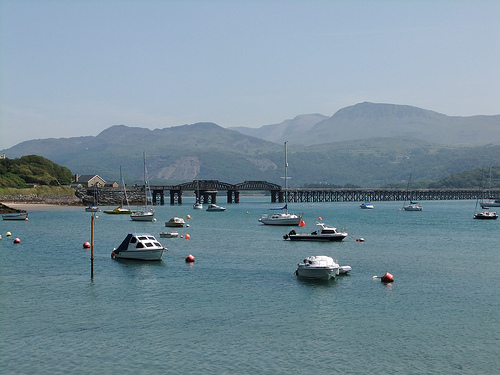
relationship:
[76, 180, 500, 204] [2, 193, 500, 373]
bridge across water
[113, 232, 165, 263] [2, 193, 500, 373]
boat on water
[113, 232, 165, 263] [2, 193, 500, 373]
boat drifting in water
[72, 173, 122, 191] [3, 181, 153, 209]
structure on bank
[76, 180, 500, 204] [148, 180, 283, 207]
bridge has suspension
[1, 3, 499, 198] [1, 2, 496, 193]
view in background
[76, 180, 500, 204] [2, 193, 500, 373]
bridge over water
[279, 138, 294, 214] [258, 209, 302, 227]
sail down on boat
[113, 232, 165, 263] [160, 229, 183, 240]
boat near boat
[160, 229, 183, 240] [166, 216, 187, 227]
boat close to boat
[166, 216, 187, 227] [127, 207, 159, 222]
boat near boat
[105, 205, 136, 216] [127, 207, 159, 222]
boat near boat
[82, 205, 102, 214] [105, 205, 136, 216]
boat near boat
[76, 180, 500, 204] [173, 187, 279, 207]
bridge boat clearance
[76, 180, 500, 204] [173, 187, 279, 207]
bridge with clearance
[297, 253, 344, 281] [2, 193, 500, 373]
boat on water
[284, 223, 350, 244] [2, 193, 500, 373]
boat on water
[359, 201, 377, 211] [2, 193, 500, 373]
boat on water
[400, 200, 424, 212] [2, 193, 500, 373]
boat on water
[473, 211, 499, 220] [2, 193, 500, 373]
boat on water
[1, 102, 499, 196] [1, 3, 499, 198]
mountains in distance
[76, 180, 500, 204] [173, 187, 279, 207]
bridge has opening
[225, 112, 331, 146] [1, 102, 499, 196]
top of mountain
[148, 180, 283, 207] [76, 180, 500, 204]
section of bridge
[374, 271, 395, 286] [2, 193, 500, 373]
floater on water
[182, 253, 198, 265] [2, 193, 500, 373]
bouy on water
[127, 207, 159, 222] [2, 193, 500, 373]
boat on water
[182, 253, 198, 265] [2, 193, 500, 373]
bouy in water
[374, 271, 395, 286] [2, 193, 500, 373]
bouy in water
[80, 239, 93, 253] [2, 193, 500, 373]
bouy in water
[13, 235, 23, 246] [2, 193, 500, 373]
bouy in water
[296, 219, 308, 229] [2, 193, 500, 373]
bouy in water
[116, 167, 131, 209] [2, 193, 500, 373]
sail boat in water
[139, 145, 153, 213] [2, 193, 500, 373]
sail boat in water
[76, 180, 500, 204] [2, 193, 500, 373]
bridge crosses water